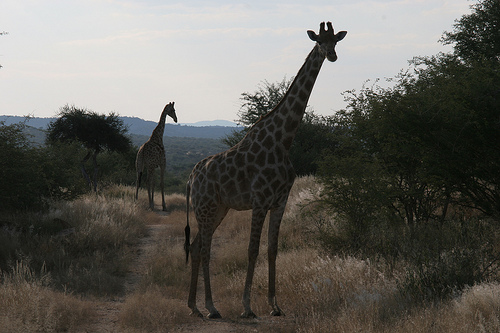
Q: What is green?
A: The trees.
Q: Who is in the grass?
A: Giraffe.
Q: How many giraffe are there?
A: Two.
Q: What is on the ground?
A: Grass.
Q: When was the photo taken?
A: Day time.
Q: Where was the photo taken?
A: In the savannah.